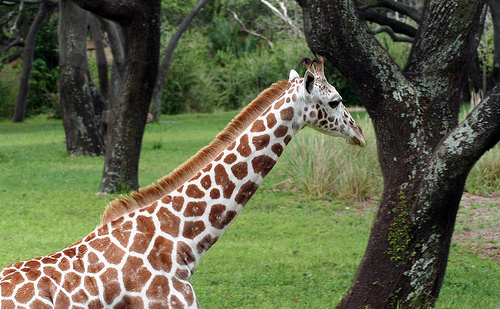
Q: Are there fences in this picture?
A: No, there are no fences.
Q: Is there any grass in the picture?
A: Yes, there is grass.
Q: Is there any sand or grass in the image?
A: Yes, there is grass.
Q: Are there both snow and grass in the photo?
A: No, there is grass but no snow.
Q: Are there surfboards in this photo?
A: No, there are no surfboards.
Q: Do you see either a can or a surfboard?
A: No, there are no surfboards or cans.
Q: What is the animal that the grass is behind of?
A: The animal is a giraffe.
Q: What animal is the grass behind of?
A: The grass is behind the giraffe.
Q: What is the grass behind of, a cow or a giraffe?
A: The grass is behind a giraffe.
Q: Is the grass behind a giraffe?
A: Yes, the grass is behind a giraffe.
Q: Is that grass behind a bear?
A: No, the grass is behind a giraffe.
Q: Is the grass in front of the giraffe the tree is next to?
A: No, the grass is behind the giraffe.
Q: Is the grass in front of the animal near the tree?
A: No, the grass is behind the giraffe.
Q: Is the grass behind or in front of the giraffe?
A: The grass is behind the giraffe.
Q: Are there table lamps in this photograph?
A: No, there are no table lamps.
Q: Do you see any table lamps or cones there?
A: No, there are no table lamps or cones.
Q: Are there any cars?
A: No, there are no cars.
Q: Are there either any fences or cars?
A: No, there are no cars or fences.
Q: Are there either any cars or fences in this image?
A: No, there are no cars or fences.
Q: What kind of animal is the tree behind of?
A: The tree is behind the giraffe.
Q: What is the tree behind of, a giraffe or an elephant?
A: The tree is behind a giraffe.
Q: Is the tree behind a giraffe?
A: Yes, the tree is behind a giraffe.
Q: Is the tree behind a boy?
A: No, the tree is behind a giraffe.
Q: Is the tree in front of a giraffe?
A: No, the tree is behind a giraffe.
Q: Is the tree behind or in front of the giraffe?
A: The tree is behind the giraffe.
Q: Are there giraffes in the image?
A: Yes, there is a giraffe.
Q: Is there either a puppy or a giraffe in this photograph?
A: Yes, there is a giraffe.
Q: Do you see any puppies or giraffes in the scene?
A: Yes, there is a giraffe.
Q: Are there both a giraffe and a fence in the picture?
A: No, there is a giraffe but no fences.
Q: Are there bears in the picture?
A: No, there are no bears.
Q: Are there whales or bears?
A: No, there are no bears or whales.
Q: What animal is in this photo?
A: The animal is a giraffe.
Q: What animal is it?
A: The animal is a giraffe.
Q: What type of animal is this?
A: That is a giraffe.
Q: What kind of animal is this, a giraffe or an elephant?
A: That is a giraffe.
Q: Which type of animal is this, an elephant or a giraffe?
A: That is a giraffe.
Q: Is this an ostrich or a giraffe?
A: This is a giraffe.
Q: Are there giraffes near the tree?
A: Yes, there is a giraffe near the tree.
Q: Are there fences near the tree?
A: No, there is a giraffe near the tree.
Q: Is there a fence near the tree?
A: No, there is a giraffe near the tree.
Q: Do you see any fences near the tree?
A: No, there is a giraffe near the tree.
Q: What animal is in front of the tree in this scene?
A: The giraffe is in front of the tree.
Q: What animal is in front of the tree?
A: The giraffe is in front of the tree.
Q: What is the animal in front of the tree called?
A: The animal is a giraffe.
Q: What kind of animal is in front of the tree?
A: The animal is a giraffe.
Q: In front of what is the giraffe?
A: The giraffe is in front of the tree.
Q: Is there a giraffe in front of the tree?
A: Yes, there is a giraffe in front of the tree.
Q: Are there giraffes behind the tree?
A: No, the giraffe is in front of the tree.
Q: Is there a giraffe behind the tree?
A: No, the giraffe is in front of the tree.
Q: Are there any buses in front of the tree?
A: No, there is a giraffe in front of the tree.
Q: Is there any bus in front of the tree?
A: No, there is a giraffe in front of the tree.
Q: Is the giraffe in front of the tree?
A: Yes, the giraffe is in front of the tree.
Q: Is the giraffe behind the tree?
A: No, the giraffe is in front of the tree.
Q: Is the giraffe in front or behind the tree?
A: The giraffe is in front of the tree.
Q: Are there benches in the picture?
A: No, there are no benches.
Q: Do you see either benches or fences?
A: No, there are no benches or fences.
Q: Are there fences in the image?
A: No, there are no fences.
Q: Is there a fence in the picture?
A: No, there are no fences.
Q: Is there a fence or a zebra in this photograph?
A: No, there are no fences or zebras.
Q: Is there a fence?
A: No, there are no fences.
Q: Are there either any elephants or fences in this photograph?
A: No, there are no fences or elephants.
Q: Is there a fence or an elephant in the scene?
A: No, there are no fences or elephants.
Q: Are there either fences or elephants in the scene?
A: No, there are no fences or elephants.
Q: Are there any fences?
A: No, there are no fences.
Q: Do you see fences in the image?
A: No, there are no fences.